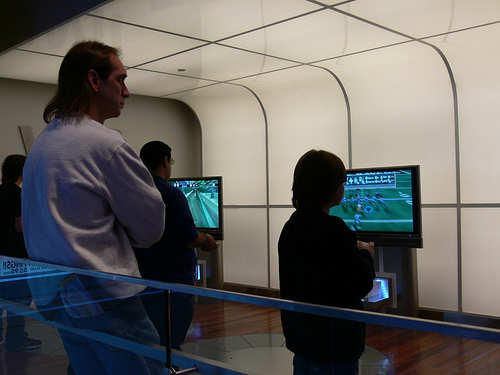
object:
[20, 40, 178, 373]
man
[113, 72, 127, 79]
eyebrow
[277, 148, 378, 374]
boy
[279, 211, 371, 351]
shirt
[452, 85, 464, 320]
lines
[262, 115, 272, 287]
lines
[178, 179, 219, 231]
screen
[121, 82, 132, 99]
nose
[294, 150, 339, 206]
hair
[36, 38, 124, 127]
hair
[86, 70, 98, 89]
ear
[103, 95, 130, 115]
mouth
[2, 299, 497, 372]
floor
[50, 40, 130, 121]
head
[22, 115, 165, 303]
shirt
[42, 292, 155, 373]
pants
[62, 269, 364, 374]
top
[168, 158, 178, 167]
glasses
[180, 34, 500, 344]
wall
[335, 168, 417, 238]
screen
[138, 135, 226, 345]
man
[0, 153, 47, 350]
man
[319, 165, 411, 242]
monitor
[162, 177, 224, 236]
frame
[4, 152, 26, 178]
hair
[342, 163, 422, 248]
frame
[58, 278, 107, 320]
pockets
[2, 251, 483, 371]
railings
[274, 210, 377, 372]
outfit